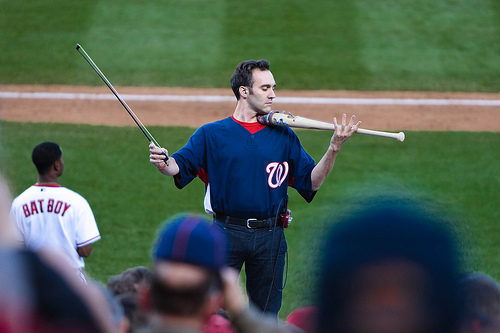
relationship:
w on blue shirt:
[262, 157, 289, 193] [170, 115, 318, 219]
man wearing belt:
[76, 21, 400, 318] [204, 197, 284, 237]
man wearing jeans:
[146, 60, 360, 325] [186, 209, 337, 316]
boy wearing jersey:
[28, 134, 126, 254] [10, 180, 103, 271]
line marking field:
[0, 89, 500, 106] [4, 0, 498, 320]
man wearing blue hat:
[137, 213, 299, 330] [156, 214, 231, 267]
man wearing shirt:
[146, 60, 360, 325] [168, 118, 319, 225]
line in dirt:
[44, 67, 174, 117] [23, 79, 213, 129]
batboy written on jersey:
[17, 197, 69, 217] [10, 184, 102, 271]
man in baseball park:
[146, 60, 360, 325] [0, 0, 498, 319]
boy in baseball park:
[4, 140, 102, 287] [0, 0, 498, 319]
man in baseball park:
[132, 213, 309, 333] [0, 0, 498, 319]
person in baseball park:
[310, 191, 465, 331] [0, 0, 498, 319]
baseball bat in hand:
[257, 111, 406, 143] [326, 111, 363, 154]